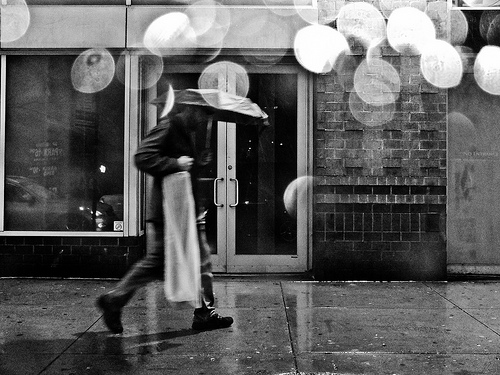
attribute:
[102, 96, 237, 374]
man — tall, wet, walking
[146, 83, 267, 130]
umbrella — black, small, short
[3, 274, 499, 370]
floor — brown, wet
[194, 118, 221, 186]
pole — umbrella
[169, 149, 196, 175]
hand — man's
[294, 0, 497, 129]
spots —  Water,  dropplet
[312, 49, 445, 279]
wall —  brick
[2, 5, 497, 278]
building — wet,  brick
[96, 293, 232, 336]
shoes —   dark 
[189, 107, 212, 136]
face —  man's, with beard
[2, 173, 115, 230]
reflection —  of  car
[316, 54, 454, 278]
wall —  brick,  patterned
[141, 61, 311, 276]
doors —   Double,  two,  glass,  building's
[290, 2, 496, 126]
drops —  rain's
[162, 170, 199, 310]
towel —  white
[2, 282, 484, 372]
sidewalk —   wet,  paved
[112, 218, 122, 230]
sticker —   for no smoking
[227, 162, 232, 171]
keyhole —  door's,  for key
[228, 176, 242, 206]
handle —  door's 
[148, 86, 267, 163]
umbrella —  open,  dark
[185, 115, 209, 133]
hair —  dark,  facial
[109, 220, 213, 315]
pants —  long